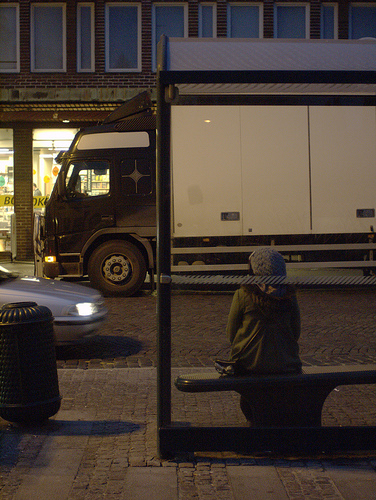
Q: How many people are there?
A: One.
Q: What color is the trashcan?
A: Black.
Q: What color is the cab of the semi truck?
A: Black.